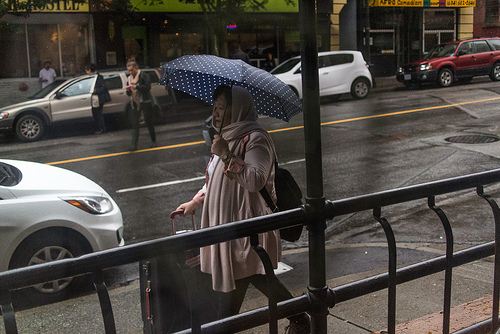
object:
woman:
[175, 84, 313, 333]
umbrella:
[156, 53, 304, 136]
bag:
[273, 165, 303, 243]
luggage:
[138, 208, 223, 333]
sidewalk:
[0, 241, 494, 332]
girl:
[123, 56, 158, 152]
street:
[0, 78, 499, 218]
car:
[268, 50, 375, 100]